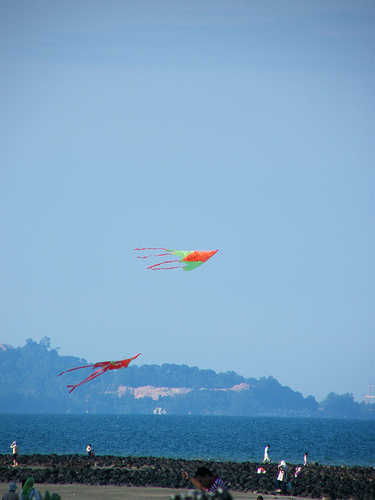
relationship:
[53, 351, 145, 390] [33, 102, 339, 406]
kite in sky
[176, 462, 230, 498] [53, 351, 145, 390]
man holding kite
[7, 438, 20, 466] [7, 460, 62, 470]
man on shore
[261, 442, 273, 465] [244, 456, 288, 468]
person on shore